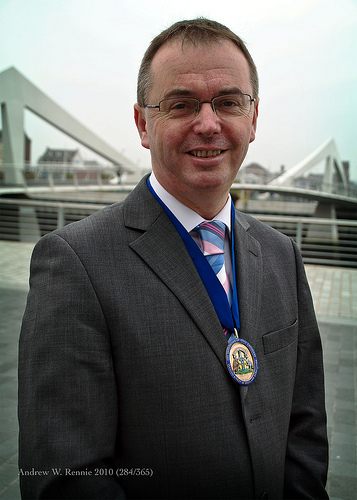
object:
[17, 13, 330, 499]
man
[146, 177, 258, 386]
medal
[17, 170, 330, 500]
suit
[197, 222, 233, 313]
tie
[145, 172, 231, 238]
shirt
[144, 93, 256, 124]
glasses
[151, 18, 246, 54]
hair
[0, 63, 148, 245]
bridge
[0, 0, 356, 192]
background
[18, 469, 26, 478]
letter a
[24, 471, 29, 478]
letter n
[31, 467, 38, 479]
letter d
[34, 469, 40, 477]
letter r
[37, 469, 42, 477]
letter e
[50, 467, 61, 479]
letter w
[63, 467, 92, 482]
word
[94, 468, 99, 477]
number 2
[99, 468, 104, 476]
number 0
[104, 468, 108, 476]
number one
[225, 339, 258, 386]
medalion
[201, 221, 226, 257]
stripe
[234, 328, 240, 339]
ring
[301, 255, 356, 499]
pavement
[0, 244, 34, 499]
pavement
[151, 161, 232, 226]
neck